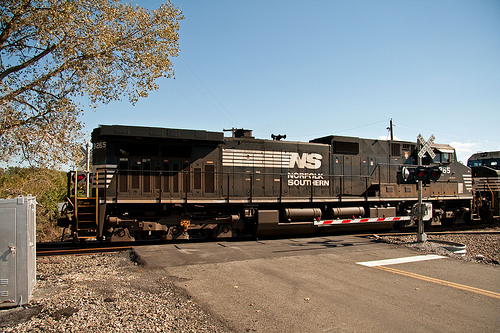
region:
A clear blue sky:
[280, 40, 340, 80]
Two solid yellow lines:
[395, 270, 445, 305]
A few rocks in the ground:
[107, 320, 120, 330]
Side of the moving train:
[250, 180, 278, 200]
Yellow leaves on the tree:
[155, 52, 170, 69]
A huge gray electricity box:
[7, 198, 37, 299]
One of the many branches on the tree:
[26, 38, 36, 50]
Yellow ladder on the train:
[75, 192, 96, 229]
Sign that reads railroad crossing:
[413, 131, 438, 159]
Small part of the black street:
[321, 292, 347, 317]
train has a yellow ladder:
[71, 171, 101, 233]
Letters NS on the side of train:
[223, 146, 329, 188]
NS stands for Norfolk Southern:
[219, 145, 331, 187]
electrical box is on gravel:
[0, 198, 42, 300]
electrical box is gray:
[1, 195, 37, 302]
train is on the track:
[68, 129, 498, 234]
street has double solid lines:
[353, 259, 498, 306]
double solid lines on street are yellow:
[369, 265, 497, 318]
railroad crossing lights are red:
[416, 163, 442, 182]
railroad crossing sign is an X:
[415, 132, 437, 159]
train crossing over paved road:
[37, 72, 480, 298]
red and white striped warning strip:
[300, 210, 415, 230]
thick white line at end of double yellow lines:
[355, 247, 482, 307]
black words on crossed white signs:
[411, 126, 436, 161]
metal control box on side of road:
[0, 187, 40, 307]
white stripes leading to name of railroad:
[215, 140, 325, 192]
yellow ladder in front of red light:
[60, 160, 110, 245]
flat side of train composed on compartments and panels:
[86, 120, 471, 211]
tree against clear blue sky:
[30, 15, 267, 105]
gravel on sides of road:
[63, 228, 483, 326]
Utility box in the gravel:
[2, 190, 44, 315]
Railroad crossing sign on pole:
[414, 131, 437, 161]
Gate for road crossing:
[313, 211, 420, 228]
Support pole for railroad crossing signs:
[412, 133, 435, 245]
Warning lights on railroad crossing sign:
[408, 164, 442, 183]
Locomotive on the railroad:
[57, 113, 478, 240]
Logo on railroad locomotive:
[218, 143, 330, 190]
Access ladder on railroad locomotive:
[68, 167, 103, 240]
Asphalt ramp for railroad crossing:
[128, 231, 396, 270]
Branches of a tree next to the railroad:
[4, 2, 182, 104]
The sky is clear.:
[190, 17, 457, 113]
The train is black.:
[52, 108, 482, 237]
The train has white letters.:
[208, 144, 357, 199]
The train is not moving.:
[50, 116, 470, 269]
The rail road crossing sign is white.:
[395, 124, 452, 246]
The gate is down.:
[302, 203, 455, 250]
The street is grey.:
[196, 257, 474, 327]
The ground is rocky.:
[43, 258, 143, 331]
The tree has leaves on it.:
[5, 5, 174, 177]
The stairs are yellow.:
[36, 98, 112, 262]